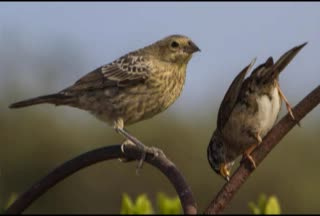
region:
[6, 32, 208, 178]
brown bird perched on a branch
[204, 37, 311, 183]
upside down bird on a branch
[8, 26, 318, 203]
two birds on a branch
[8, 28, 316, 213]
pair of birds on a branch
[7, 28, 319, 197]
two sparrows perched on a branch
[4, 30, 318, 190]
mother bird with baby bird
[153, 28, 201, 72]
face of the sparrow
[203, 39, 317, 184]
bird perched upside down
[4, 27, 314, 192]
two sparrows in a tree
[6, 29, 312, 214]
two birds in a tree with yellow flowers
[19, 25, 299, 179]
birds on a tree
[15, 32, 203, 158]
bird on a branch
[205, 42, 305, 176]
bird facing downward on branch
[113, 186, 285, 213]
green leaves on branch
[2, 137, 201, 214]
branch with a loop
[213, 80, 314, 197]
branch that is straight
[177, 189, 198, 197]
white spot on branch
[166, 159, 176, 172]
white knob on branch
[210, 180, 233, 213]
knobs on the branch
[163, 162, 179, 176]
knob on curved branch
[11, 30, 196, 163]
the bird is on a branch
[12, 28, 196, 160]
the bird is looking right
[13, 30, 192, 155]
the bird is resting on a branch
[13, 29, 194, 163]
the bird is stading on a brach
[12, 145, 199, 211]
the branch is curved down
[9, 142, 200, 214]
the branch is brown in color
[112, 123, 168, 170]
the birds claws are holding on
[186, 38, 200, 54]
the bird's beak is black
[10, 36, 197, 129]
the bird is covered with feathers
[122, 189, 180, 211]
green leaves are behind the bird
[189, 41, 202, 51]
the beak of a bird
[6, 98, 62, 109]
the tail of a bird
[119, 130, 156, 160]
the leg of a bird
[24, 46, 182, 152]
a bird resting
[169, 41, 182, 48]
the eye of a bird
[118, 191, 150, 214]
the leaves of a plant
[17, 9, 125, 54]
clear skies in the distant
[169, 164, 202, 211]
a metal pole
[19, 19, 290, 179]
two birds on a metal pole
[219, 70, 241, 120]
the wing of a bird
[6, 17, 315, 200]
two birds perched on branches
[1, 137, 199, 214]
bent wooden branch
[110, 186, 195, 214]
green tops of plants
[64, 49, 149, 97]
feathered wing of bird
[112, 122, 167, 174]
bird leg and claw on branch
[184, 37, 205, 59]
brown beak on bird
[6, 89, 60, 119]
tail of bird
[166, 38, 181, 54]
one black bird eye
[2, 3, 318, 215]
blurred brown and blue background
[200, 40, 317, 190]
bird rubbing beak on branch